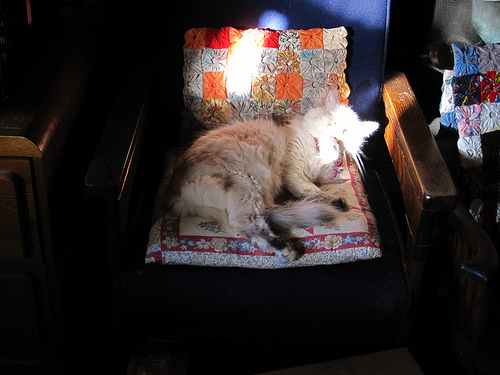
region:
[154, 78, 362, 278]
cat on blanket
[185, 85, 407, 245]
small cat on blanket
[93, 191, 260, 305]
blanket below white cat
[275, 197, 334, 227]
tail on a blanket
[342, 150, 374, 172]
white cat whiskers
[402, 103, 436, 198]
brown arm of chair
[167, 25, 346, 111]
pillow on chair back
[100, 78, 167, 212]
brown arm of chair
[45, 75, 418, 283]
cat sleeping on chair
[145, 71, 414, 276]
cat sleeping on pillow and blanket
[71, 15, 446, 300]
cat licking its hand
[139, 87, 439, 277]
cat licking its paw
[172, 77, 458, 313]
cat licking its front paw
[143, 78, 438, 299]
white and black cat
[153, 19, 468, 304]
kitty laying in sun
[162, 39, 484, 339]
kitty cleaning itself in sun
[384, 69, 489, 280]
wooden brown arm of chair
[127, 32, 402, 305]
cat laying on pillow in chair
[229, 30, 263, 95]
light shining on the pillow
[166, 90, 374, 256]
a house cat sleeping on the chair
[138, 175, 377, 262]
a pillow under the cat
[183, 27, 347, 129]
a flower pattern on the pillow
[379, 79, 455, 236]
a wooden arm rest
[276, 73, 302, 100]
an orange flower patch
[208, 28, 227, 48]
a red flower patch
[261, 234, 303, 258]
black spot on the cat's leg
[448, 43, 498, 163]
pillow sitting next to the chair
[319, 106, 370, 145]
light on the cat's face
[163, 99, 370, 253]
white and black cat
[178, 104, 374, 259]
cat laying on pillow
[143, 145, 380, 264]
pillow sitting on chair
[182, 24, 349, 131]
patched pillow on chair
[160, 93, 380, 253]
cat laying on chair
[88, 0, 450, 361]
blue fabric and wood chair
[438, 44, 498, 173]
blanket next to chair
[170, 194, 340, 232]
white and black tail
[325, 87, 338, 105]
white ear of cat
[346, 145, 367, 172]
white whiskers on cat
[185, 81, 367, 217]
A brown cat on a chair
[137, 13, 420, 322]
A big black seat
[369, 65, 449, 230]
A big black seat handle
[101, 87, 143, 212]
A big black seat handle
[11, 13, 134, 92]
A dark photo background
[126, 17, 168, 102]
A dark photo background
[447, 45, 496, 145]
A multi colored seat cover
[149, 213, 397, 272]
A multi colored seat cover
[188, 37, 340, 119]
A multi colored seat cover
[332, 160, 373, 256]
A multi colored seat cover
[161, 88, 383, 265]
Fluffy cat lying on chair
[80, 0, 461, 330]
Blue armchair with wooden arms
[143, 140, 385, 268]
Cushion with flowered red border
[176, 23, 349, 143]
Unusual multicolored pillow on chair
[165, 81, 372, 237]
the cat is laying down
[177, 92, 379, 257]
the cat is white in color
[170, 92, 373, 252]
the cat is sleeping on a chair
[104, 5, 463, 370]
the chair is made of wood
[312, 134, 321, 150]
the collar is red in color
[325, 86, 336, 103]
the cat's ear is pointy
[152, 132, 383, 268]
the cat is sleeping on a cushion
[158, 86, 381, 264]
A long-haired cat laying down